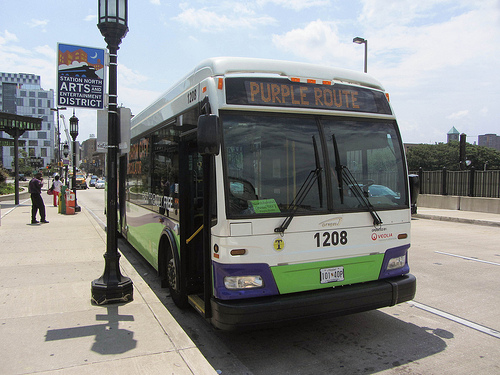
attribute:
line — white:
[413, 294, 498, 352]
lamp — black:
[90, 0, 134, 307]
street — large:
[436, 197, 487, 292]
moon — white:
[89, 48, 100, 60]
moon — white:
[90, 47, 100, 63]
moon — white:
[87, 49, 107, 64]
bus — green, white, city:
[119, 50, 446, 345]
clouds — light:
[390, 10, 495, 127]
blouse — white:
[51, 180, 62, 193]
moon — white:
[86, 44, 108, 71]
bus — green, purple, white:
[102, 52, 417, 335]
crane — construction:
[58, 111, 70, 153]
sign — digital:
[219, 69, 398, 122]